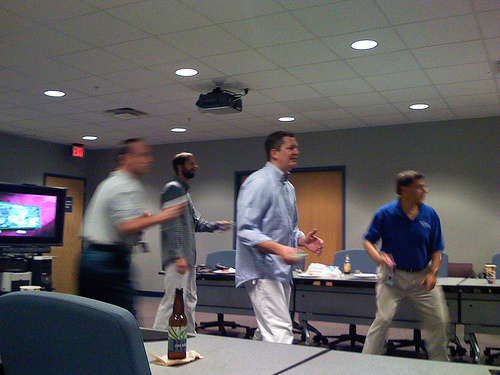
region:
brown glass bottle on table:
[165, 285, 187, 360]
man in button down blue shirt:
[232, 128, 324, 344]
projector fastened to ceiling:
[191, 83, 243, 118]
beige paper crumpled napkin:
[150, 346, 202, 366]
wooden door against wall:
[234, 166, 346, 264]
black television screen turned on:
[2, 180, 69, 247]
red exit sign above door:
[69, 143, 88, 160]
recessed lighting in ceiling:
[350, 37, 377, 52]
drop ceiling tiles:
[2, 2, 496, 145]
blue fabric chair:
[2, 285, 150, 372]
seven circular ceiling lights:
[43, 38, 430, 145]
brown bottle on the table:
[166, 288, 188, 359]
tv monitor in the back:
[0, 181, 65, 251]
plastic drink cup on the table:
[485, 263, 497, 283]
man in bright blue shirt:
[363, 168, 450, 360]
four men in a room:
[79, 136, 454, 361]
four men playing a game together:
[73, 129, 451, 363]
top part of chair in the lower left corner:
[0, 292, 152, 374]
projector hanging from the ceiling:
[192, 83, 247, 115]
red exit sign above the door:
[71, 144, 83, 158]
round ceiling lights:
[337, 22, 441, 125]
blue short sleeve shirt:
[361, 194, 449, 271]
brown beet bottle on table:
[163, 279, 196, 361]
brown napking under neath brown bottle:
[147, 345, 204, 368]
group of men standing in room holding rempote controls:
[74, 122, 458, 362]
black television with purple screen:
[1, 175, 70, 252]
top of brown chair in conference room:
[0, 285, 154, 373]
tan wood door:
[229, 165, 352, 287]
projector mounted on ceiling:
[188, 85, 263, 125]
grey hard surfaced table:
[147, 326, 494, 373]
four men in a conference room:
[79, 140, 449, 356]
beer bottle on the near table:
[168, 288, 186, 359]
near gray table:
[137, 329, 492, 374]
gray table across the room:
[187, 267, 498, 330]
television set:
[2, 188, 64, 243]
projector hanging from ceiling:
[197, 90, 243, 115]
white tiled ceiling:
[0, 2, 498, 142]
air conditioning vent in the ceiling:
[107, 105, 142, 122]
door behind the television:
[49, 178, 81, 283]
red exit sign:
[73, 144, 85, 155]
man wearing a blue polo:
[359, 169, 464, 374]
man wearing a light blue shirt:
[225, 116, 349, 353]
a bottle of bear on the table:
[157, 285, 200, 364]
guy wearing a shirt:
[69, 130, 177, 342]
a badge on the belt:
[382, 259, 401, 290]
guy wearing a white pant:
[221, 127, 343, 350]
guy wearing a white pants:
[355, 162, 465, 365]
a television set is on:
[0, 172, 87, 247]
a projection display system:
[181, 72, 272, 127]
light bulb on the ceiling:
[345, 34, 378, 56]